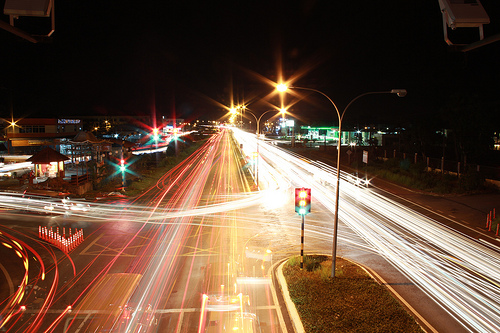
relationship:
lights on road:
[150, 195, 269, 253] [68, 135, 499, 325]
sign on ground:
[358, 150, 370, 165] [339, 159, 411, 196]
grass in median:
[305, 276, 366, 311] [273, 243, 433, 332]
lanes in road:
[184, 128, 246, 331] [68, 135, 499, 325]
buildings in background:
[11, 111, 373, 167] [29, 138, 402, 140]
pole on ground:
[344, 146, 354, 166] [339, 159, 411, 196]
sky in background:
[5, 3, 499, 128] [29, 138, 402, 140]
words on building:
[55, 117, 84, 126] [4, 114, 107, 178]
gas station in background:
[296, 118, 376, 151] [29, 138, 402, 140]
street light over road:
[275, 75, 412, 279] [68, 135, 499, 325]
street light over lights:
[275, 75, 412, 279] [150, 195, 269, 253]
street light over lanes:
[275, 75, 412, 279] [184, 128, 246, 331]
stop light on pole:
[292, 185, 315, 217] [300, 214, 309, 269]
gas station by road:
[296, 118, 376, 151] [68, 135, 499, 325]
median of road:
[273, 243, 433, 332] [68, 135, 499, 325]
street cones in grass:
[484, 206, 499, 235] [305, 276, 366, 311]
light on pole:
[117, 165, 127, 170] [344, 146, 354, 166]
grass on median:
[305, 276, 366, 311] [273, 243, 433, 332]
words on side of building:
[55, 117, 84, 126] [4, 114, 107, 178]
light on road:
[117, 165, 127, 170] [68, 135, 499, 325]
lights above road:
[150, 195, 269, 253] [68, 135, 499, 325]